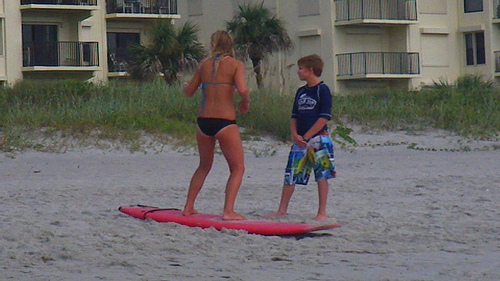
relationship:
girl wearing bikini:
[177, 29, 254, 221] [192, 60, 240, 144]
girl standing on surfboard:
[177, 29, 254, 221] [90, 170, 348, 250]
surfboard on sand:
[114, 191, 346, 251] [78, 206, 417, 279]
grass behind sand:
[5, 72, 169, 147] [14, 153, 241, 272]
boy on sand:
[269, 48, 349, 228] [247, 206, 397, 279]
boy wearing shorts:
[261, 51, 335, 220] [280, 119, 340, 197]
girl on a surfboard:
[177, 29, 254, 221] [105, 180, 351, 249]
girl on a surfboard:
[177, 29, 254, 221] [106, 185, 348, 255]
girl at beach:
[176, 21, 254, 234] [3, 86, 478, 256]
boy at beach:
[261, 51, 335, 220] [3, 72, 482, 264]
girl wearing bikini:
[176, 21, 254, 234] [189, 64, 243, 145]